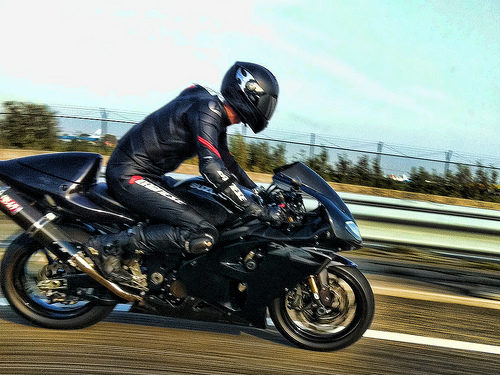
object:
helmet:
[221, 61, 279, 135]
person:
[82, 61, 288, 284]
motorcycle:
[0, 151, 375, 353]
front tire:
[269, 254, 376, 353]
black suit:
[105, 83, 262, 258]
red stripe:
[197, 134, 222, 157]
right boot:
[80, 221, 145, 283]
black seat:
[87, 182, 133, 215]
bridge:
[0, 101, 500, 175]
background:
[0, 0, 499, 203]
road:
[0, 211, 500, 374]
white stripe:
[0, 297, 500, 355]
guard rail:
[97, 166, 500, 265]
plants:
[0, 102, 500, 202]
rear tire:
[0, 230, 117, 330]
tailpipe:
[0, 181, 143, 300]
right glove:
[201, 156, 292, 228]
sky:
[0, 0, 500, 180]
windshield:
[273, 161, 365, 249]